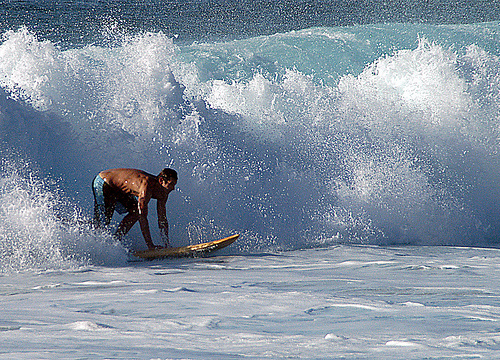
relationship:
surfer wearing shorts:
[91, 167, 180, 257] [91, 172, 139, 222]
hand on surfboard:
[165, 243, 173, 247] [135, 233, 239, 259]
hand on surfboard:
[148, 243, 163, 249] [135, 233, 239, 259]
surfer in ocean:
[91, 167, 180, 257] [2, 1, 497, 360]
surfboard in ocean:
[135, 233, 239, 259] [2, 1, 497, 360]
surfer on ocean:
[91, 167, 180, 257] [0, 13, 497, 272]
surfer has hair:
[91, 167, 180, 257] [158, 167, 178, 180]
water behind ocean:
[1, 0, 498, 51] [0, 13, 497, 272]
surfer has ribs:
[91, 167, 180, 257] [119, 180, 138, 196]